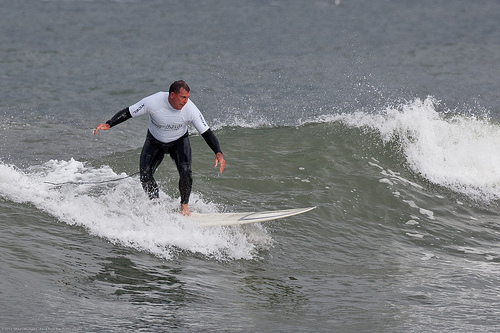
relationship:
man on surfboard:
[93, 80, 225, 217] [149, 200, 319, 227]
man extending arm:
[93, 80, 225, 217] [78, 92, 271, 166]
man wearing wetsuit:
[93, 80, 225, 217] [103, 91, 222, 205]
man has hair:
[93, 80, 225, 217] [167, 76, 190, 93]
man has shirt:
[93, 80, 225, 217] [129, 91, 211, 143]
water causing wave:
[3, 2, 496, 329] [3, 109, 498, 231]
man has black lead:
[93, 80, 225, 217] [41, 172, 140, 186]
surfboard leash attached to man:
[76, 171, 113, 191] [138, 65, 215, 137]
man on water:
[93, 80, 225, 217] [3, 2, 496, 329]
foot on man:
[177, 205, 191, 219] [93, 80, 225, 217]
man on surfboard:
[93, 80, 225, 217] [167, 195, 321, 226]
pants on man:
[141, 131, 192, 203] [93, 80, 225, 217]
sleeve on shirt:
[191, 114, 222, 156] [102, 89, 231, 158]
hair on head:
[169, 78, 191, 94] [168, 80, 190, 109]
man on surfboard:
[100, 76, 262, 233] [86, 163, 341, 245]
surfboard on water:
[154, 209, 316, 224] [29, 199, 444, 331]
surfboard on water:
[179, 205, 317, 225] [3, 2, 496, 329]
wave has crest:
[0, 103, 497, 256] [212, 96, 432, 146]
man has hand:
[93, 80, 225, 217] [210, 151, 228, 178]